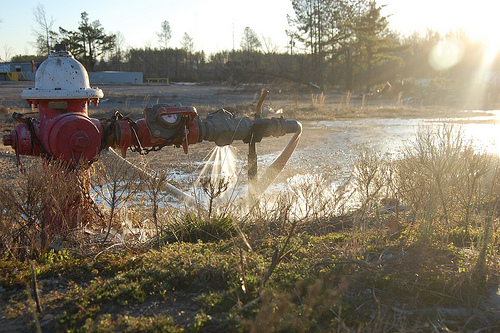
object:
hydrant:
[1, 48, 120, 232]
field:
[0, 247, 290, 333]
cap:
[18, 47, 106, 99]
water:
[200, 145, 242, 189]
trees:
[193, 27, 268, 90]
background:
[109, 2, 409, 79]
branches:
[462, 217, 500, 288]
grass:
[191, 256, 241, 308]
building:
[92, 67, 144, 84]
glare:
[435, 33, 489, 65]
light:
[468, 0, 498, 66]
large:
[306, 115, 412, 191]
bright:
[181, 4, 289, 39]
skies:
[5, 0, 145, 30]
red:
[42, 114, 97, 159]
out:
[202, 143, 239, 190]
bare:
[292, 166, 391, 209]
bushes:
[394, 152, 461, 209]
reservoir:
[290, 126, 343, 178]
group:
[291, 0, 387, 100]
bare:
[27, 6, 56, 25]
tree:
[56, 14, 125, 65]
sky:
[136, 6, 261, 34]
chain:
[130, 139, 169, 156]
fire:
[251, 121, 305, 189]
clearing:
[110, 84, 164, 97]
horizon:
[118, 11, 266, 54]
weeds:
[258, 200, 321, 262]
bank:
[237, 202, 391, 283]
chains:
[68, 179, 100, 218]